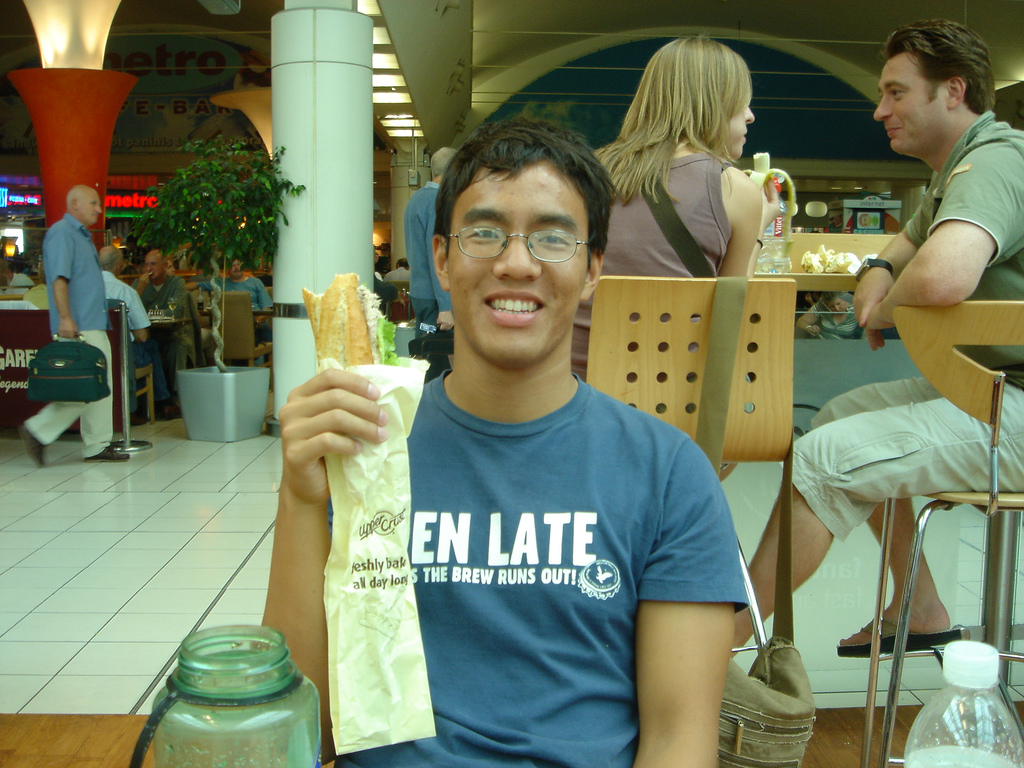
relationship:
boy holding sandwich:
[263, 117, 732, 765] [295, 278, 406, 365]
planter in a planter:
[129, 126, 305, 371] [150, 130, 297, 365]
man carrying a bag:
[24, 184, 127, 469] [30, 338, 108, 406]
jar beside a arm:
[147, 629, 326, 763] [256, 484, 324, 731]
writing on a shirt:
[409, 513, 618, 596] [346, 379, 746, 766]